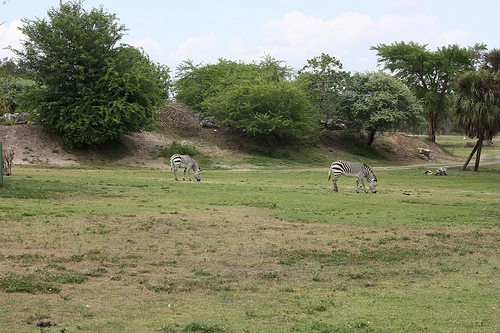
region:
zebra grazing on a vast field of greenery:
[324, 157, 381, 196]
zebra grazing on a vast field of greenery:
[167, 149, 205, 184]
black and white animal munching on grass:
[322, 158, 381, 197]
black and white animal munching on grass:
[169, 149, 202, 181]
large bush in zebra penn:
[16, 2, 167, 159]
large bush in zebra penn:
[166, 54, 312, 146]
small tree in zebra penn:
[340, 68, 427, 158]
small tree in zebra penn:
[446, 73, 498, 177]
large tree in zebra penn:
[382, 39, 489, 154]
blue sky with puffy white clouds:
[4, 4, 498, 61]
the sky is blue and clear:
[112, 3, 274, 39]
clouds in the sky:
[258, 13, 406, 53]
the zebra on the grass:
[160, 143, 202, 189]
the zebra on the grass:
[318, 145, 388, 206]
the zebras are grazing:
[157, 150, 391, 203]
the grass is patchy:
[18, 171, 498, 331]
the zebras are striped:
[152, 135, 398, 207]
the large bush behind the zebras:
[40, 5, 146, 133]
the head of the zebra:
[189, 163, 204, 183]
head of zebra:
[364, 170, 383, 192]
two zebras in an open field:
[164, 145, 381, 203]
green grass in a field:
[8, 162, 497, 331]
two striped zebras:
[163, 151, 378, 196]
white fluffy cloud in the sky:
[4, 13, 471, 58]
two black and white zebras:
[166, 151, 379, 193]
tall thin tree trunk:
[471, 136, 483, 172]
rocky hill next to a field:
[2, 119, 449, 167]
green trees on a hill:
[14, 0, 470, 144]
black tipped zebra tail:
[324, 166, 331, 179]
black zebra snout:
[196, 176, 201, 181]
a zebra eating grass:
[315, 149, 395, 197]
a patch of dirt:
[90, 282, 136, 309]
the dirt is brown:
[85, 274, 120, 297]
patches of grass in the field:
[295, 263, 379, 303]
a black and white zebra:
[161, 148, 211, 186]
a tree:
[447, 82, 489, 174]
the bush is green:
[202, 62, 303, 134]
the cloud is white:
[260, 18, 333, 46]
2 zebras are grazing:
[162, 143, 421, 217]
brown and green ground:
[79, 212, 361, 329]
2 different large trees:
[385, 37, 497, 159]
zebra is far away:
[157, 140, 224, 197]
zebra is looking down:
[170, 148, 239, 192]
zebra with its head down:
[313, 150, 412, 232]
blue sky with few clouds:
[156, 17, 376, 91]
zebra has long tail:
[322, 153, 343, 180]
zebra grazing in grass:
[325, 158, 386, 205]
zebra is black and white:
[323, 157, 380, 194]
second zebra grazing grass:
[167, 153, 204, 188]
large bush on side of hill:
[3, 1, 167, 147]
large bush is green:
[2, 1, 172, 156]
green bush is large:
[1, 0, 171, 164]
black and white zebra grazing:
[323, 152, 385, 212]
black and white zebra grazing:
[167, 146, 213, 205]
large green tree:
[20, 8, 166, 163]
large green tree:
[340, 71, 418, 152]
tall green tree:
[380, 25, 461, 154]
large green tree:
[452, 50, 497, 175]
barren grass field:
[5, 160, 498, 331]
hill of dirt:
[4, 120, 64, 168]